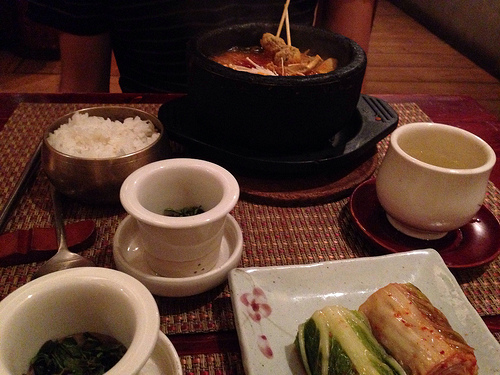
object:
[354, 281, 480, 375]
food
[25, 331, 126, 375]
food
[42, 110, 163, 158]
food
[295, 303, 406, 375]
food